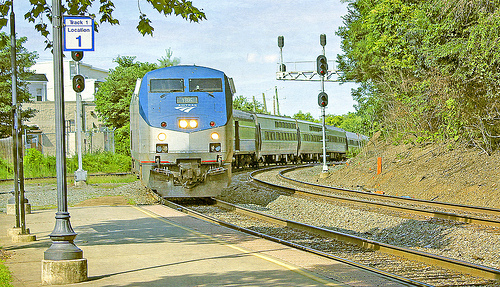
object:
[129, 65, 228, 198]
locomotive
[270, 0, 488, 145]
green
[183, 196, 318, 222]
gravel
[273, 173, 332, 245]
tracks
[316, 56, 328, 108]
railroad signals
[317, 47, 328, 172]
pole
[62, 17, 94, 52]
sign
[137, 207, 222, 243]
line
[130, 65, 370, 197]
train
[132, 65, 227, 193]
front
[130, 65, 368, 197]
car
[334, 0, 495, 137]
tree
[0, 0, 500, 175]
leaves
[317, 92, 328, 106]
traffic signal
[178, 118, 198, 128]
lights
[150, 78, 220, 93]
window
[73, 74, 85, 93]
stop light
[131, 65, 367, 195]
passenger train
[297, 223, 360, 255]
railroad crossing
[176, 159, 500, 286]
railroad tracks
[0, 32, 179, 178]
bushes